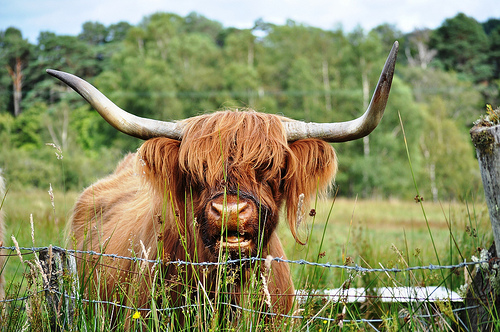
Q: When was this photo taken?
A: During the day.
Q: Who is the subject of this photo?
A: The ox.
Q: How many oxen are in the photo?
A: One.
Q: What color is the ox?
A: Brown.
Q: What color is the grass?
A: Green.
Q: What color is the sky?
A: Blue.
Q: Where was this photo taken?
A: In a zoo.